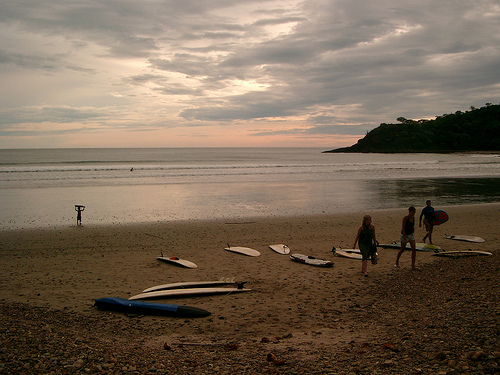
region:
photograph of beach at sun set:
[22, 16, 474, 344]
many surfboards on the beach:
[105, 201, 485, 336]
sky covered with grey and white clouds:
[35, 17, 450, 134]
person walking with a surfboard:
[412, 188, 454, 245]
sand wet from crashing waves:
[185, 160, 494, 222]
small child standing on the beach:
[56, 190, 101, 232]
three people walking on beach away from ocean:
[329, 192, 458, 277]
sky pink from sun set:
[85, 111, 357, 153]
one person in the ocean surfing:
[119, 152, 149, 182]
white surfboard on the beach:
[220, 230, 265, 267]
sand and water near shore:
[8, 142, 482, 359]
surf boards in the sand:
[129, 225, 498, 306]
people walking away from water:
[350, 195, 455, 276]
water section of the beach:
[21, 145, 315, 180]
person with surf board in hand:
[420, 203, 451, 248]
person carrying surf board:
[73, 198, 95, 231]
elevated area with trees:
[355, 100, 487, 153]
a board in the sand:
[151, 245, 201, 272]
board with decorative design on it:
[283, 253, 334, 271]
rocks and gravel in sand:
[425, 315, 485, 362]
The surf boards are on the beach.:
[89, 226, 489, 321]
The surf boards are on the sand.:
[103, 230, 489, 316]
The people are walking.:
[340, 198, 442, 272]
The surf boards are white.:
[107, 225, 482, 310]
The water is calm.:
[8, 151, 496, 210]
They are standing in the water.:
[58, 192, 93, 233]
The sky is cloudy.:
[8, 1, 483, 147]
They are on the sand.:
[343, 194, 465, 283]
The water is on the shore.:
[11, 175, 497, 246]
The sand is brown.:
[35, 234, 482, 369]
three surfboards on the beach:
[152, 233, 299, 273]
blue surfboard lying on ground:
[63, 295, 211, 331]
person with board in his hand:
[417, 198, 442, 243]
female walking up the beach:
[352, 193, 387, 298]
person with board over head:
[63, 194, 88, 239]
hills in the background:
[376, 106, 496, 156]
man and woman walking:
[339, 199, 419, 294]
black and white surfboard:
[287, 248, 344, 280]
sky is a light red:
[30, 120, 319, 151]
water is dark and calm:
[103, 165, 498, 202]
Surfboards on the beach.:
[148, 220, 352, 317]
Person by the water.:
[60, 186, 155, 246]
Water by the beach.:
[76, 120, 283, 245]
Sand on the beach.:
[106, 208, 376, 338]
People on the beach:
[350, 165, 492, 310]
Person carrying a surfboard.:
[416, 187, 456, 253]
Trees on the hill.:
[292, 76, 499, 166]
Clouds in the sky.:
[130, 30, 317, 142]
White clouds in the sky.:
[148, 24, 313, 153]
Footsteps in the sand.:
[232, 255, 340, 372]